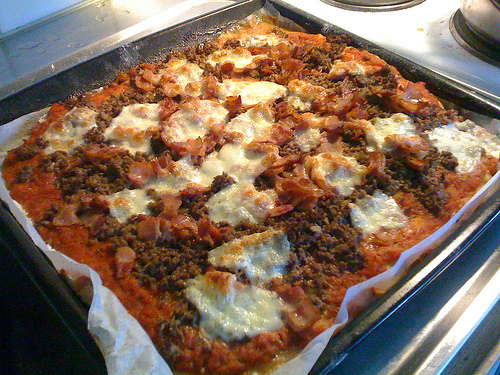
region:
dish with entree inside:
[4, 13, 499, 373]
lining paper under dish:
[78, 275, 142, 367]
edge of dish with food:
[84, 33, 131, 50]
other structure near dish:
[428, 3, 498, 57]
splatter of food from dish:
[415, 17, 426, 44]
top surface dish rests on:
[11, 23, 86, 42]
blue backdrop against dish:
[0, 6, 30, 23]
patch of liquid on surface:
[3, 33, 50, 60]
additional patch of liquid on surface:
[83, 4, 137, 23]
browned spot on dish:
[177, 28, 212, 38]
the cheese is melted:
[109, 113, 304, 289]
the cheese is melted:
[288, 135, 403, 224]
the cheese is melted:
[104, 112, 246, 224]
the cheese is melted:
[188, 168, 282, 298]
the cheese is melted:
[198, 123, 303, 208]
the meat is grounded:
[75, 98, 217, 275]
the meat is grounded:
[289, 215, 347, 292]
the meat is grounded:
[386, 158, 443, 216]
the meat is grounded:
[255, 61, 314, 96]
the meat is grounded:
[322, 113, 384, 170]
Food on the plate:
[176, 19, 353, 223]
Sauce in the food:
[169, 111, 209, 141]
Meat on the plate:
[298, 217, 340, 269]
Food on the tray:
[89, 99, 341, 276]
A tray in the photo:
[39, 268, 77, 338]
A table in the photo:
[408, 310, 484, 342]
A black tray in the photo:
[28, 264, 90, 324]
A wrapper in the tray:
[94, 301, 151, 368]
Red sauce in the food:
[46, 200, 90, 262]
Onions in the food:
[285, 163, 309, 204]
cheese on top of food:
[178, 262, 300, 337]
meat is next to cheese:
[274, 209, 369, 288]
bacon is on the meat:
[107, 150, 203, 244]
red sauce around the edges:
[25, 175, 72, 233]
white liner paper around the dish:
[70, 272, 152, 369]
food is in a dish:
[1, 6, 498, 373]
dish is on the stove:
[286, 18, 421, 74]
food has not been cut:
[20, 24, 498, 374]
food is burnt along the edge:
[63, 5, 265, 85]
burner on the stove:
[335, 0, 440, 12]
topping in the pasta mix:
[161, 265, 188, 282]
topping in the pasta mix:
[312, 262, 329, 279]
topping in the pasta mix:
[254, 301, 274, 315]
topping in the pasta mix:
[381, 215, 403, 235]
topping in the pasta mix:
[304, 215, 326, 232]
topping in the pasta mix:
[413, 168, 434, 188]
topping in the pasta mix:
[247, 195, 267, 217]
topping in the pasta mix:
[202, 144, 228, 173]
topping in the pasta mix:
[163, 248, 175, 260]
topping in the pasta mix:
[226, 333, 254, 361]